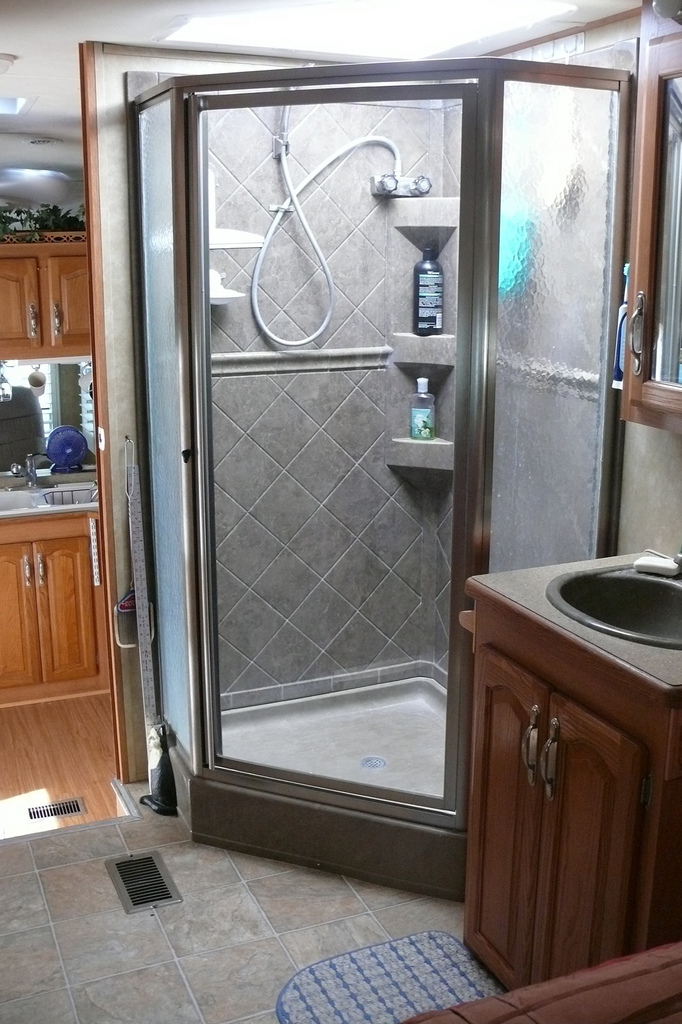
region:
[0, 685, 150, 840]
The hardwood floor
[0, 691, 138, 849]
A hardwood floor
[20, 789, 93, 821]
The square metal grid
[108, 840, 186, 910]
A square metal vent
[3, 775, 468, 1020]
The tiled floor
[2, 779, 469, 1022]
A tiled floor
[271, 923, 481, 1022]
The blue and white mat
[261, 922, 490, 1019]
A blue and white mat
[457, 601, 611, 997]
The brown cabinets in the bathroom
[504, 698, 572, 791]
The handles on the wooden cabinet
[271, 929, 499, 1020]
A blue rug in front of the sink.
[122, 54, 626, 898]
A small shower with glass doors.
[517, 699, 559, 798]
Door handles on the bathroom cabinet.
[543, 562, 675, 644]
The basin in the bathroom.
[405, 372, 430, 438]
A soap bottle in the shower.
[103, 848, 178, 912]
A vent on the bathroom floor.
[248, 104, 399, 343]
The white hose in the shower.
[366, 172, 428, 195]
The hot and cold handles in the shower.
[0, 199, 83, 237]
A plant on top of the kitchen cabinets.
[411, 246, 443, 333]
Large dark colored bottle in the shower.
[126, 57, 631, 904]
empty shower stall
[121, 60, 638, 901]
a silver bathroom shower stall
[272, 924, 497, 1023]
a blue and white bath rug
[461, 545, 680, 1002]
one brown bathroom vanity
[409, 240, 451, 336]
black bottle of shampoo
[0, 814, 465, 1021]
gray tile on a bathroom floor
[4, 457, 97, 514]
white kitchen sink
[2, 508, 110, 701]
brown kitchen cabinets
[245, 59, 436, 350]
one hand-held shower head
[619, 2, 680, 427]
one brown medicine cabinet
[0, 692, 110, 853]
brown hardwood floor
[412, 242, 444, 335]
black and white plastic bottle in shower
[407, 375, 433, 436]
clear plastic bottle with blue label in shower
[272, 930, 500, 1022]
blue and green rug on tiled floor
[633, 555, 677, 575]
white bar of soap on sink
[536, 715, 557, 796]
bronze door handle on wood cabinet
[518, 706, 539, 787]
bronze door handle on wood cabinet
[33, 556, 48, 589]
bronze door handle on wood cabinet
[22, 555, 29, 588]
bronze door handle on wood cabinet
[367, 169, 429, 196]
water control knobs in shower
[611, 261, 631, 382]
blue and white electric toothbrush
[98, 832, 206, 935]
vent is on the floor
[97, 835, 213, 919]
vent is silver in color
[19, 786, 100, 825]
vent is on the wood floor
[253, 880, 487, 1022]
bath mat in front of sink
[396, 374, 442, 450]
bottle has a blue label on it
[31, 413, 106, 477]
blue fan above kitchen sink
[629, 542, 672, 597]
soap on the bathroom sink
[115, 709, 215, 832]
cat decoration is on the floor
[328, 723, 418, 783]
drain is on the shower floor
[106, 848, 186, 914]
a gray floor vent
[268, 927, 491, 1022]
a blue and gray rug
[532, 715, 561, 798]
a cabinet handle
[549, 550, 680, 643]
a bathroom sink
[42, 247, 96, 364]
A door for a cabinet.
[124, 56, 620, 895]
shower in a restroom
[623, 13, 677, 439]
mirror in a restroom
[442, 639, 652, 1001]
cabinets under the sink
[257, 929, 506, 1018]
rug in front of the sink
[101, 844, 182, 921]
heat vent on the floor